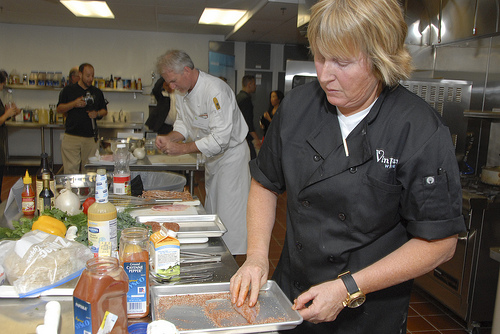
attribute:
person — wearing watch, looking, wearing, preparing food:
[228, 2, 471, 328]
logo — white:
[377, 146, 399, 173]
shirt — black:
[231, 106, 473, 329]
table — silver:
[3, 187, 251, 333]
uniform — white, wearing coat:
[164, 75, 260, 263]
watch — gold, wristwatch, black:
[337, 272, 369, 311]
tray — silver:
[146, 277, 307, 333]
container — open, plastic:
[116, 226, 164, 320]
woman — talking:
[257, 87, 284, 131]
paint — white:
[2, 25, 218, 78]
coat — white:
[161, 81, 255, 170]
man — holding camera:
[80, 92, 104, 112]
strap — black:
[338, 269, 358, 297]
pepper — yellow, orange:
[32, 215, 70, 239]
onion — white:
[52, 189, 80, 213]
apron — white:
[209, 143, 253, 259]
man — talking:
[231, 75, 269, 161]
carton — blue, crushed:
[72, 255, 130, 333]